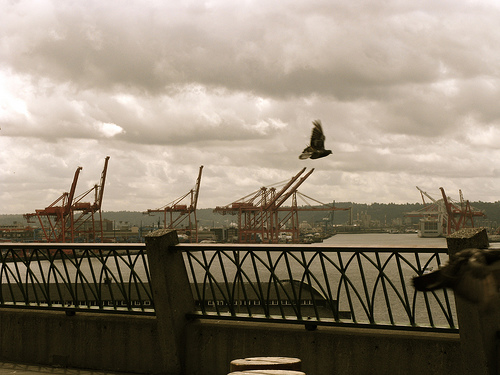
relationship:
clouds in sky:
[1, 0, 499, 203] [0, 0, 498, 204]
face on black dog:
[404, 241, 487, 318] [403, 234, 498, 369]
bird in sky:
[294, 113, 336, 164] [0, 0, 498, 204]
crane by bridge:
[401, 186, 486, 236] [0, 226, 499, 373]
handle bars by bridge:
[0, 240, 500, 253] [0, 226, 499, 373]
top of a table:
[230, 355, 300, 366] [227, 354, 304, 373]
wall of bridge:
[0, 305, 499, 373] [0, 226, 499, 373]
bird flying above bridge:
[297, 116, 333, 159] [0, 206, 455, 361]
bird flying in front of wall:
[297, 116, 333, 159] [3, 230, 498, 372]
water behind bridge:
[314, 226, 454, 296] [55, 227, 443, 371]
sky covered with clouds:
[0, 0, 498, 204] [1, 0, 499, 203]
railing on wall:
[2, 238, 492, 335] [3, 230, 498, 372]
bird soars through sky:
[297, 116, 333, 159] [0, 0, 498, 204]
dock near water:
[2, 279, 351, 308] [335, 228, 420, 268]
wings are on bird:
[308, 118, 327, 156] [312, 119, 328, 156]